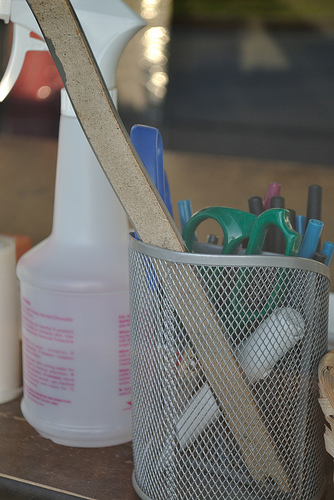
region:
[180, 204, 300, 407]
scissors with green handle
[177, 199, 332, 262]
four blue pen caps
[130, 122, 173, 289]
blue scissor handle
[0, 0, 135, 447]
white and clear spray bottle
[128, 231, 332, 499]
silver metal writing utensil holder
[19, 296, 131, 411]
small pink text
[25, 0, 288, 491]
processed wood straightedge rectangle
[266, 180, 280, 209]
pink pen cap in holder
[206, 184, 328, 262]
five black pen caps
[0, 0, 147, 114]
white and plastic sprayer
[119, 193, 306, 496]
a silver wire container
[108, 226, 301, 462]
a container that is silver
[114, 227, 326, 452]
a container made from wire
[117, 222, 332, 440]
a ruler in a container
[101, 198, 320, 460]
scissors in a container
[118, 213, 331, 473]
pens in a container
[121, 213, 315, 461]
container with a ruler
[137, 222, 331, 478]
container with scissors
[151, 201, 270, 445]
pens in a container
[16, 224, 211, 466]
a bottle for cleaner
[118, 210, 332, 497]
an all purpose holder for many desk items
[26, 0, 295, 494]
a ruler in this container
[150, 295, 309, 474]
a stick of chalk in a holder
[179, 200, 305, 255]
top of a pair of scissors visible in this container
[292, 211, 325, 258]
ball point pens with blue tops in this container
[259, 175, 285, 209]
a purple topped pen in this container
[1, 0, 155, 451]
a spray bottle sitting next to the container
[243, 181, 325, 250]
several black ball point pens with black tops in this container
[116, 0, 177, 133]
something gold and shiny in the background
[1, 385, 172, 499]
container and spray bottle sit on a worn wooden shelf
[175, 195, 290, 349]
scissors' handles are green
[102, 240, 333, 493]
a gray metal pen holder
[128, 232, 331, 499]
Gray wire pencil holder.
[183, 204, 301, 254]
Handle of green scissors.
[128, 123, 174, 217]
Handle of blue scissors.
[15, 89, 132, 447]
Part of a plastic spray bottle.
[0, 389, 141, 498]
A brown colored desktop.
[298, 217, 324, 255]
A blue colored pen cap.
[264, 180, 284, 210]
A purple colored pen cap.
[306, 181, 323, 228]
A black colored pen cap.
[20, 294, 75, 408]
Pink print on plastic.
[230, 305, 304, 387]
A white object in pencil holder.